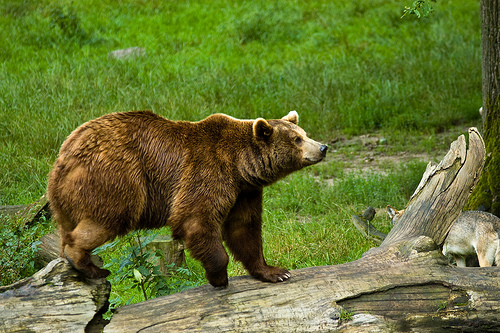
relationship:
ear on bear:
[251, 117, 274, 139] [39, 99, 336, 290]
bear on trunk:
[39, 99, 336, 290] [0, 226, 498, 331]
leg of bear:
[52, 215, 140, 311] [39, 99, 336, 290]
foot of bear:
[253, 255, 294, 289] [44, 108, 327, 288]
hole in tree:
[337, 281, 469, 316] [0, 127, 499, 332]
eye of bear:
[282, 131, 307, 148] [39, 99, 336, 290]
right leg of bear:
[170, 209, 227, 289] [51, 99, 337, 313]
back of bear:
[78, 106, 253, 154] [47, 82, 349, 302]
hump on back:
[204, 107, 236, 131] [78, 106, 253, 154]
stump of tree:
[33, 220, 105, 270] [462, 0, 499, 217]